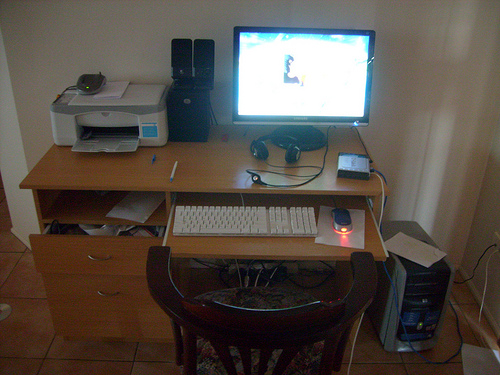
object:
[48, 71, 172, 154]
printer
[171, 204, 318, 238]
keyboard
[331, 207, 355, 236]
mouse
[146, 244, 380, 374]
chair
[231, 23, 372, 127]
monitor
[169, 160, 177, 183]
pen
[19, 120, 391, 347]
desk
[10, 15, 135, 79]
wall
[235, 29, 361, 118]
screen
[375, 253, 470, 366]
computer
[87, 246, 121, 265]
handle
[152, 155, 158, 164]
cap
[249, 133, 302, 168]
headphone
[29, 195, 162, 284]
drawer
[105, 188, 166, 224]
paper